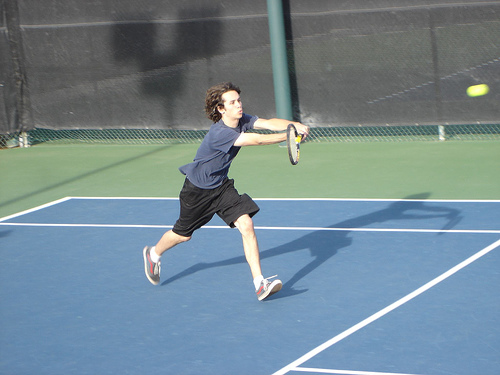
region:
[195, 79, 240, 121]
Man has brown hair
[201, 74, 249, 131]
Man's hair is windblown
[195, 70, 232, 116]
Man's hair is curly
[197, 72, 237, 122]
Man's hair is long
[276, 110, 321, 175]
Man holding tennis racket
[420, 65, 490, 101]
Tennis ball flying through air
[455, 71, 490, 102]
Tennis ball is bright yellow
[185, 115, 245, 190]
Man wearing a gray T shirt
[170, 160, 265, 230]
Man wearing black shorts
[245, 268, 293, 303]
Man wearing athletic shoe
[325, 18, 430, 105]
The net is black.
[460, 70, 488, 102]
The ball is yellow.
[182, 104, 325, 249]
He is wearing a blue shirt.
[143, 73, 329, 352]
He is swinging a racket.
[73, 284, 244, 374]
The ground is blue.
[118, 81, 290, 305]
He is wearing black pants.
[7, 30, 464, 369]
He is on a tennis court.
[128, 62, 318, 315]
He is running.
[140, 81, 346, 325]
He is playing tennis.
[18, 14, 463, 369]
It is a nice day outside.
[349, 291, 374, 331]
the line is white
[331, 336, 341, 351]
the line is white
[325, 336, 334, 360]
the line is white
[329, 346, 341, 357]
the line is white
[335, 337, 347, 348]
the line is white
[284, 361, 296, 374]
the line is white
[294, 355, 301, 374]
the line is white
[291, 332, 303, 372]
the line is white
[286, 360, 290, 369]
the line is white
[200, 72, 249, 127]
the head of a person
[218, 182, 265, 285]
the leg of a person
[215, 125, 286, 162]
the arm of a person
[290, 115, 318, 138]
the hand of a person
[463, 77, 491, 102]
a green tennis ball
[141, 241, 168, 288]
a gray, red, and white shoe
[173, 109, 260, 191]
a gray tee shirt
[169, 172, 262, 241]
a pair of black shorts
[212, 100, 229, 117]
the ear of a person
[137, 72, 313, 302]
a person on the tennis court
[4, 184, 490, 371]
Light blue tennis court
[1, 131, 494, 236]
Light green tennis court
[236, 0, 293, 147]
Thick green metal pole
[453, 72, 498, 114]
Tennis ball in motion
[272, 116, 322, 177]
Black and white tennis racquet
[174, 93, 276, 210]
Blue tee shirt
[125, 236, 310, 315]
Red white and black tennis shoes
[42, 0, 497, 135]
Green fence with black covering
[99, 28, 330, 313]
Young man preparing to hit tennis ball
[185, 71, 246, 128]
Curly brown hair